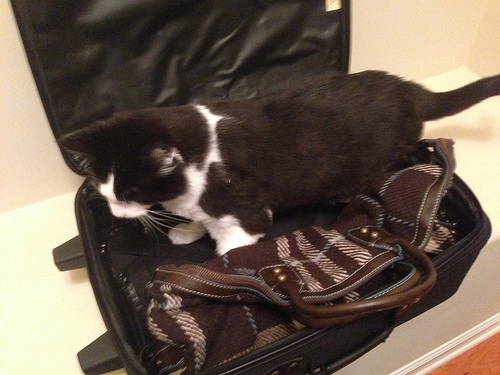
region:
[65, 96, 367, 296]
the cat that is black and white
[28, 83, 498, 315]
a black suit case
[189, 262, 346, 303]
a brown purse inside a suitcase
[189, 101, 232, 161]
the white part of the cat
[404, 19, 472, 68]
the white wall behind the suit case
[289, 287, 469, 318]
the handle of the purse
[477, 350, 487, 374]
some wood on the side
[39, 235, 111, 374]
two legs of the suitcase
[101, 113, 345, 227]
a cat in a suit case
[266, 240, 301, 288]
two buttons on the purse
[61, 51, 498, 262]
a black and white colored cat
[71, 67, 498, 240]
the cat is in the suitcase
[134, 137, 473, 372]
a brown and white bad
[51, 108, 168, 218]
the cat's head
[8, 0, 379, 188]
the flap of the bag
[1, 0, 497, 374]
the bag is black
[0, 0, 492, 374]
the bag is open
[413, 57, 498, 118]
this is a cat's tail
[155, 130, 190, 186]
this is the cats ear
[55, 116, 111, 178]
this is the cats ear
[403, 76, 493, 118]
black tail of small cat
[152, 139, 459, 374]
brown and white purse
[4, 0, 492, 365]
cat standing in suitcase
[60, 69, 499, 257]
white and black cat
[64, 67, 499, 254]
short hair black and white cat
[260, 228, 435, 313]
purse with brown strap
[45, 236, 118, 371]
two black luggage pegs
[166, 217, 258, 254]
white furry paws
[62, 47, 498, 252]
short hair cat looking down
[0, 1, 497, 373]
luggage sitting on white table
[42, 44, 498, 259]
black cat in a suitcase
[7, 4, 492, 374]
black suitcase with a cat inside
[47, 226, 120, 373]
legs for a suitcase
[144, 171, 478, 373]
brown purse in suitcase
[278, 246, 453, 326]
brown handles to a purse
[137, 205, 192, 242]
white whiskers on a cat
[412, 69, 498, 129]
tail of a cat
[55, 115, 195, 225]
head of a cat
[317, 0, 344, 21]
tag on a suitcase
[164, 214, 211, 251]
front paw of a suitcase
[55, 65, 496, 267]
Cat sitting inside suitcase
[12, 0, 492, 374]
Suitcase is black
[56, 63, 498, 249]
Cat is black and white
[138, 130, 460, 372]
Brown bag next to cat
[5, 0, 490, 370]
Black suitcase on top of dresser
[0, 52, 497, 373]
Dresser is white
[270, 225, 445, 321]
Brown handle on brown bag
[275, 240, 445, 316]
Handle is brown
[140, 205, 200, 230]
White whisker on cat's face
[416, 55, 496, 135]
Tail is long and black